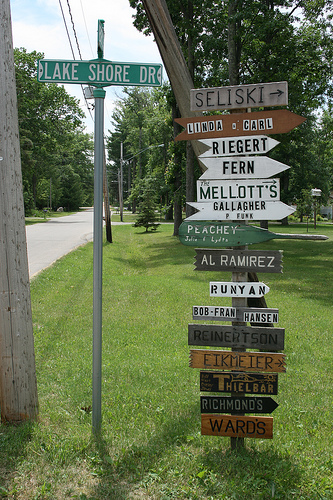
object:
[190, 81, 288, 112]
sign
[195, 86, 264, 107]
seliski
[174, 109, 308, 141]
sign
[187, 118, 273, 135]
linda and carl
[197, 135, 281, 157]
sign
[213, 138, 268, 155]
riegert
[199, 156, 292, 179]
sign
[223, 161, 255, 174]
fern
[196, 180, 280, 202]
sign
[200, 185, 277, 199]
mellott's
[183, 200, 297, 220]
sign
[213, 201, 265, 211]
gallagher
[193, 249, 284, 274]
sign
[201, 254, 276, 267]
al ramirez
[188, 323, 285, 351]
sign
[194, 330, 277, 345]
reinertson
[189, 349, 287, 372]
sign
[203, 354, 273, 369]
eikmeier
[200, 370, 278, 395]
sign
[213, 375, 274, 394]
thielbar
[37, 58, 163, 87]
sign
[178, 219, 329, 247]
sign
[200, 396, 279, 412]
sign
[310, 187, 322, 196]
bird house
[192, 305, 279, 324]
signs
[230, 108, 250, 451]
pole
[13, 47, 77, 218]
tree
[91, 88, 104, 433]
pole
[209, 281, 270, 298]
sign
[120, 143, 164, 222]
streetlight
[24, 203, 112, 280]
road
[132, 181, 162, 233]
pine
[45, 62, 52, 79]
letter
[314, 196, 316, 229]
post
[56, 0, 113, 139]
wires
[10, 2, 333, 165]
sky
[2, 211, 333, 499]
grass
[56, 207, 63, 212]
rock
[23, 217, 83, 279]
ground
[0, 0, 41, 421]
pole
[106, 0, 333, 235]
trees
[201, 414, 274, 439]
sign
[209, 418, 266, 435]
ward's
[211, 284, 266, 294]
runyan